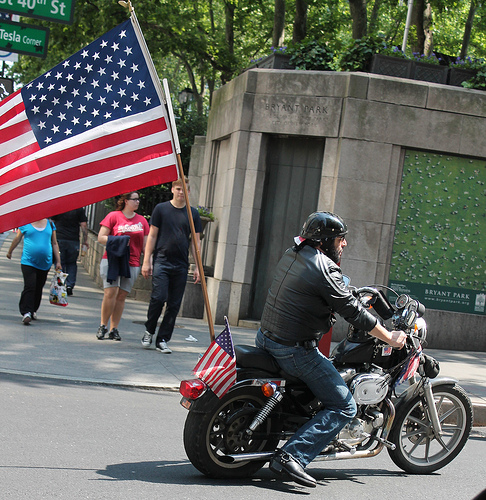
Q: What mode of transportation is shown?
A: Motorcycle.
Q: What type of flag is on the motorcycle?
A: American.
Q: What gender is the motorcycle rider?
A: Male.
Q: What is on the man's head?
A: Helmet.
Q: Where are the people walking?
A: Sidewalk.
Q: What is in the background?
A: Trees.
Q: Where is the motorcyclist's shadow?
A: Under and behind the motorcycle.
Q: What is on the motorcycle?
A: American flag.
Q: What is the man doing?
A: Riding a bike.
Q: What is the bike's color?
A: Black.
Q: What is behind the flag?
A: Some people.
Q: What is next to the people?
A: A gray building.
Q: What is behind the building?
A: Some trees.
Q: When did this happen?
A: During the day time.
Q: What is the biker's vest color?
A: Black.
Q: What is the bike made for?
A: Driving around.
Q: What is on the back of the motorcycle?
A: Flags.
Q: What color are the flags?
A: Red, white and blue.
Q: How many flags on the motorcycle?
A: Two.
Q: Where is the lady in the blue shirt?
A: On the sidewalk.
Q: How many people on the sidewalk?
A: Four.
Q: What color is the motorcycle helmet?
A: Black.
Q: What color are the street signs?
A: Green.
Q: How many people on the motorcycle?
A: One.